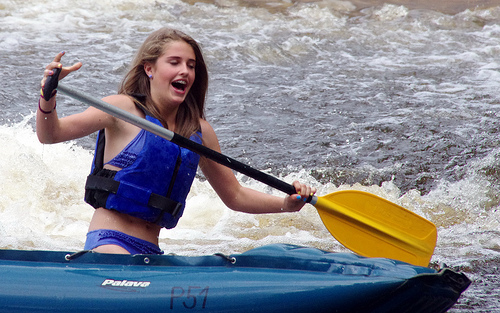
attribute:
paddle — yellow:
[40, 66, 437, 272]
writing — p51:
[163, 279, 212, 311]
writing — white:
[97, 270, 156, 292]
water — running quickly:
[2, 1, 496, 311]